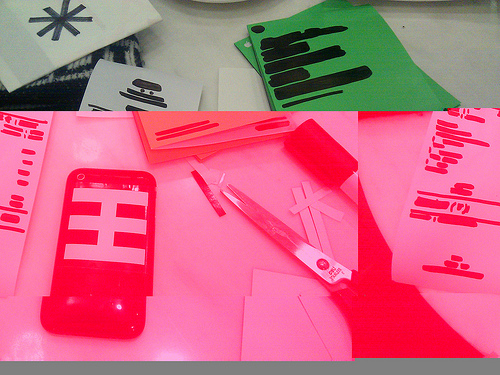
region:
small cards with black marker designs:
[21, 6, 432, 112]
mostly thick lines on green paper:
[247, 16, 397, 101]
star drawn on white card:
[16, 5, 116, 50]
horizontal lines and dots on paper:
[80, 65, 186, 106]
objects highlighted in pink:
[20, 121, 480, 337]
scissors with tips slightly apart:
[201, 167, 367, 322]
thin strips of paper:
[286, 175, 346, 265]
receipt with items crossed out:
[405, 110, 486, 297]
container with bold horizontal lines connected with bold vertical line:
[40, 165, 180, 340]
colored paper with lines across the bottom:
[133, 112, 285, 152]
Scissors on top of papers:
[218, 175, 405, 357]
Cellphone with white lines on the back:
[60, 155, 157, 370]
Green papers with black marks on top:
[244, 35, 456, 126]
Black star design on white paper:
[19, 7, 193, 76]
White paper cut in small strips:
[289, 171, 352, 298]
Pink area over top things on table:
[10, 80, 481, 341]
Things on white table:
[128, 22, 498, 89]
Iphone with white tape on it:
[46, 136, 146, 347]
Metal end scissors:
[224, 169, 408, 352]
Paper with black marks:
[425, 136, 477, 303]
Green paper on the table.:
[224, 10, 498, 146]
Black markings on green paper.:
[264, 27, 377, 99]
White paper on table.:
[89, 58, 242, 118]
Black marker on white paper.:
[98, 66, 185, 121]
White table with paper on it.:
[166, 16, 271, 96]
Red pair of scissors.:
[176, 144, 456, 364]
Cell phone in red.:
[17, 153, 165, 363]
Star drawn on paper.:
[25, 1, 146, 56]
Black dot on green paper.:
[252, 20, 281, 42]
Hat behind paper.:
[17, 40, 202, 111]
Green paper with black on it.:
[201, 21, 422, 132]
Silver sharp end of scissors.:
[227, 106, 362, 315]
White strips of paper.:
[287, 170, 342, 302]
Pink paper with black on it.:
[391, 131, 493, 336]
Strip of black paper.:
[173, 169, 241, 235]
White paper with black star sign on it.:
[2, 2, 125, 53]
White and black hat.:
[0, 35, 173, 107]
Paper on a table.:
[17, 30, 445, 159]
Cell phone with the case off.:
[33, 170, 169, 370]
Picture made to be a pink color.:
[51, 92, 445, 372]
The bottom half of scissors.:
[206, 185, 442, 363]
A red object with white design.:
[42, 161, 155, 351]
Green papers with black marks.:
[233, 0, 461, 110]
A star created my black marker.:
[3, 1, 115, 55]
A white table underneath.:
[181, 22, 229, 63]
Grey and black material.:
[32, 45, 137, 85]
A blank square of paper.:
[233, 268, 318, 366]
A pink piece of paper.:
[0, 110, 47, 287]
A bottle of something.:
[283, 120, 368, 192]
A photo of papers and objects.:
[1, 5, 498, 373]